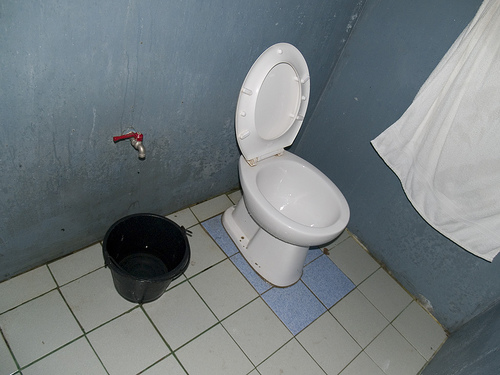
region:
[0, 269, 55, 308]
white tile on floor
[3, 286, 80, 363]
white tile on floor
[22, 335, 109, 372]
white tile on floor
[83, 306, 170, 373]
white tile on floor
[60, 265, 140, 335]
white tile on floor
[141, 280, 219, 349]
white tile on floor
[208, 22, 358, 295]
toilet lid open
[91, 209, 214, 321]
Black Bucket underneath the faucet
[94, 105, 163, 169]
Faucet mounted in the wall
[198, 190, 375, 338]
Blue tiles different than the others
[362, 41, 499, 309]
Towel hanging on the wall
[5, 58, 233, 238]
water stains on the wall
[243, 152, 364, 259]
Toilet bowl is clean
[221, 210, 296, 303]
toilet base needs cleaning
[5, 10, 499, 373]
Bathroom has no baseboards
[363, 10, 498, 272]
Towel is white in color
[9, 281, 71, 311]
white tile on floor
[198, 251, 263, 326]
white tile on floor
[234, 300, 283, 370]
white tile on floor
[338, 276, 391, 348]
white tile on floor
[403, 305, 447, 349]
white tile on floor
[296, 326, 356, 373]
white tile on floor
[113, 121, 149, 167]
A water spigot sticking out of a wall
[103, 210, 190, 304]
A small black bucket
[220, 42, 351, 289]
A white ceramic toilet with a plastic lid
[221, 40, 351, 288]
A white toilet with the lid open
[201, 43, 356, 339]
A white toilet set on blue tiles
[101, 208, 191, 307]
A round bucket sitting on white square tiles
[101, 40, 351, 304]
A bucket and a toilet on white and blue tiles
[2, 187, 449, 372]
White ceramic tile with blue accent tile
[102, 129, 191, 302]
A bucket sitting under a water spigot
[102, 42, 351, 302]
A bucket sitting on the floor beside a toilet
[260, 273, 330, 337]
tile on the floor of dirty bathroom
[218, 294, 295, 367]
tile on the floor of dirty bathroom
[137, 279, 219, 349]
tile on the floor of dirty bathroom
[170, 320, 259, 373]
tile on the floor of dirty bathroom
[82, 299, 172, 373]
tile on the floor of dirty bathroom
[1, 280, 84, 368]
tile on the floor of dirty bathroom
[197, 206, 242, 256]
tile on the floor of dirty bathroom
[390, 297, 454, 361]
tile on the floor of dirty bathroom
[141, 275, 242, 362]
A tile in a floor.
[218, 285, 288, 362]
A tile in a floor.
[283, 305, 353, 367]
A tile in a floor.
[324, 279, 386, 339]
A tile in a floor.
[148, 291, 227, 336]
A tile in a floor.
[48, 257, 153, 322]
A tile in a floor.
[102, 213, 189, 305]
black bucket sitting on restroom floor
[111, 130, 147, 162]
silver spout affixed to the wall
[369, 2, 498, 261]
white towel hanging up to the window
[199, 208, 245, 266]
blue tile under the toilet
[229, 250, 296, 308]
blue tile under the toilet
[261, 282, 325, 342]
blue tile under the toilet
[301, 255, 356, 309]
blue tile under the toilet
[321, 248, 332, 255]
small piece of debris sitting near the toilet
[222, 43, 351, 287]
white toilet with the lid up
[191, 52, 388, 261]
toilet in the bathroom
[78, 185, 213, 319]
bucket next to toilet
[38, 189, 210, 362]
black bucket next to toilet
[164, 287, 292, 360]
lines on the ground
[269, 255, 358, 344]
blue tile under toilet